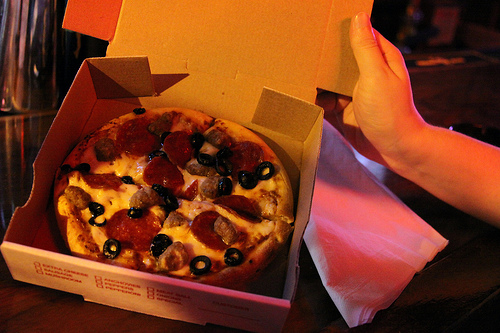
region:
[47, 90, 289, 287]
Personal pan pizza.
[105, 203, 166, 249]
Pepperoni on pizza.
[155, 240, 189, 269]
Sausage on pizza.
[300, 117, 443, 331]
Napkin on table.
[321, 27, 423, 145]
Hand on box.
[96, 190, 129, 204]
Cheese on pizza.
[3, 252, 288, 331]
Box on table.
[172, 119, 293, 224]
Slice of pizza.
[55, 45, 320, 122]
flaps on box.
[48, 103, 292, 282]
Pizza with olives and pepperoni.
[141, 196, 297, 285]
A slice of pizza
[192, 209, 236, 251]
A piece of pepperoni and sausage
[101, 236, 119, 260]
A sliced black olive.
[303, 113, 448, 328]
Pink tissue paper.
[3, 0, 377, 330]
A cardboard pizza box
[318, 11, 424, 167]
A hand holding a pizza box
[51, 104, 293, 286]
Thick crust pizza with toppings.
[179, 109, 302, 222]
Slice of olive and sausage pizza.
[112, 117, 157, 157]
Piece of pepperoni.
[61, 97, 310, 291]
This is a pizza.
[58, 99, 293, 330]
The toppings are pepperoni, olives, chicken, cheese.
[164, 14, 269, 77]
Box is brown in color.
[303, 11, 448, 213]
The person is holding the box.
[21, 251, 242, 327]
the letters are red in color.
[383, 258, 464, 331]
the person wears black color dress.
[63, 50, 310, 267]
The pizza is kept in the box.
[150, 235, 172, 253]
Olives are black in color.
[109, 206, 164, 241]
Pepperoni is red in color.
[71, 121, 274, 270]
Cheese is white in color.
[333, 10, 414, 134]
a hand holding cardboard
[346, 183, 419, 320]
a white napkin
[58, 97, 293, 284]
a pizza with pepperoni, sausage and olives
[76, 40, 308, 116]
corrugated cardboard box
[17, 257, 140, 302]
printed text on a cardboard box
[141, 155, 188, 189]
a pepperoni and cheese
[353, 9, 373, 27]
a person's fingernail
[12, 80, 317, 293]
a pizza in a box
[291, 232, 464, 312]
a folded napkin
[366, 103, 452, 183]
the wrist of a person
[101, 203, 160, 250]
Round pepperoni on pizza.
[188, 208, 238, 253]
Round pepperoni on pizza.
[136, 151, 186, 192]
Round pepperoni on pizza.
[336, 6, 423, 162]
Hand holding box.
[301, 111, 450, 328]
White napkin on table.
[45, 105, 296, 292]
Small pizza inside brown box.